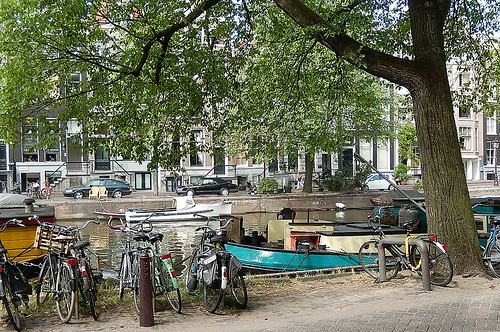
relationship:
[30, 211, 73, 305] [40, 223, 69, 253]
bicycle with a basket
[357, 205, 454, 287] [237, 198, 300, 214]
bicycle in front of water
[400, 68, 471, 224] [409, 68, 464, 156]
tree has a trunk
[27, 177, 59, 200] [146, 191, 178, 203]
people standing on sidewalk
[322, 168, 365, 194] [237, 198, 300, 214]
bushes next to water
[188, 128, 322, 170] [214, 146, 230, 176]
building has a door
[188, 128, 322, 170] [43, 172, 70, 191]
building has stairs